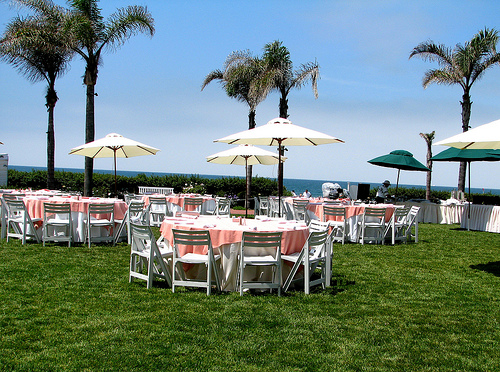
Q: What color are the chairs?
A: White.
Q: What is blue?
A: Sky.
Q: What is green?
A: Grass.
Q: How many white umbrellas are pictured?
A: Four.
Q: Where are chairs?
A: Around tables.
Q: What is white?
A: Chairs.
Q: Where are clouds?
A: In the sky.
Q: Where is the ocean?
A: In the distance.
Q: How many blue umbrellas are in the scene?
A: Two.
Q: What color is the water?
A: Blue.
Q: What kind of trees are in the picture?
A: Palm trees.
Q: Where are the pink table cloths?
A: On the tables.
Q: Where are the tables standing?
A: On the grass.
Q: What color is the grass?
A: Green.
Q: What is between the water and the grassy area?
A: A hedge.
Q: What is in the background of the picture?
A: An ocean.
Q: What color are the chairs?
A: White.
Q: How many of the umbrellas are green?
A: 2.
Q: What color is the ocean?
A: Blue.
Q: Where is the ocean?
A: Behind the palm trees.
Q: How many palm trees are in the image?
A: Five.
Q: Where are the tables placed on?
A: Grass.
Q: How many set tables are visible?
A: Four.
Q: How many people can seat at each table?
A: Ten.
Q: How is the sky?
A: Clear.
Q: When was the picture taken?
A: During daytime.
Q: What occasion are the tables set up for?
A: A reception.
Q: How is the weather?
A: Clear and sunny.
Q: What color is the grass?
A: Green.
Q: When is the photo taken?
A: During the day.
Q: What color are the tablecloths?
A: Pink.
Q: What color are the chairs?
A: White.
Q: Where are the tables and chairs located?
A: Near a beach.